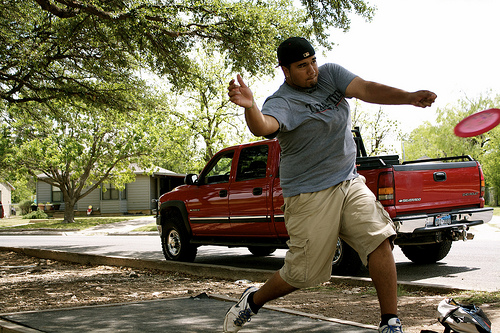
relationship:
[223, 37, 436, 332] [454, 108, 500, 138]
man throwing frisbee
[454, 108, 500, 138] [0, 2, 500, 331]
frisbee flies in air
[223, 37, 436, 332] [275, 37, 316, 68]
man has cap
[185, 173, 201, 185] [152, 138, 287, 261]
mirror of side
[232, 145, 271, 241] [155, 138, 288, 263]
door of truck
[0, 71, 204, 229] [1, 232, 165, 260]
tree on street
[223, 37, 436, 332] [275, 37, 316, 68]
man wearing cap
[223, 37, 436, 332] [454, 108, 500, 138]
man playing frisbee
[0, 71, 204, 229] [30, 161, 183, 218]
tree in front of house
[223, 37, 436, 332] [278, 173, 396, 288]
man wearing shorts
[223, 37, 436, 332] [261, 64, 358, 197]
man wearing shirt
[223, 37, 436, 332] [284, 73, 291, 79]
man wears earring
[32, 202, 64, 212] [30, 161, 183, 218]
row in front of house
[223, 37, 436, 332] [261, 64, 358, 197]
man in shirt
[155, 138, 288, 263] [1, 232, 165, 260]
truck on street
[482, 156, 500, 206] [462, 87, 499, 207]
house amongst tree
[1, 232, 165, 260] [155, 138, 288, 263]
street under truck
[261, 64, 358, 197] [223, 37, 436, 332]
shirt on man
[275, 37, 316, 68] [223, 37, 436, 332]
cap on man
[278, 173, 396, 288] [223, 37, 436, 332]
shorts on man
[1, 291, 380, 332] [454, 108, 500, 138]
sidewalk under frisbee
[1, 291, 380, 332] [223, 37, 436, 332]
sidewalk under man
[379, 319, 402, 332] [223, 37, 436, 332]
shoe worn by man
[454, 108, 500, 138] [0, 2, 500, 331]
frisbee flying thru air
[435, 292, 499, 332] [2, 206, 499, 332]
pack on ground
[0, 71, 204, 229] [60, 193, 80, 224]
tree with trunk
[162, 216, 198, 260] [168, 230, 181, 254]
tire with rim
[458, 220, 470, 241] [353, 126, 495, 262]
hitch on truck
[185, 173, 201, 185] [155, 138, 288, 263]
mirror on truck